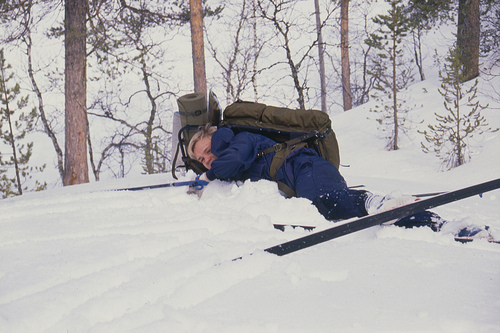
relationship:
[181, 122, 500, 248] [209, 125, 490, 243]
skier wearing suit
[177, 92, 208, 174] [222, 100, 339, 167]
bedroll on backpack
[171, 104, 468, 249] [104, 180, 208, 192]
skier has pole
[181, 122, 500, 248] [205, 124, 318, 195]
skier in jacket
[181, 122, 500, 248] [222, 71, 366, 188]
skier wearing backpack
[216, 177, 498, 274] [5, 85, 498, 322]
metal ski in snow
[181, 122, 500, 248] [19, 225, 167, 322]
skier laying on snow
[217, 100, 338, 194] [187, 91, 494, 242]
backpack of skier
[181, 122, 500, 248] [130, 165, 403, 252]
skier laying in snow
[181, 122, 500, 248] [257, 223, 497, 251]
skier wearing ski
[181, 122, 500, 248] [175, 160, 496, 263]
skier laying in snow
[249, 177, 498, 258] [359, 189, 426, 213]
ski attached to foot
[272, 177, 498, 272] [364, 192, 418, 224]
metal ski attached to ski boots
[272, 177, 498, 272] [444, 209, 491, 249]
metal ski attached to boot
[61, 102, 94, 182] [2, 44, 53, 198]
trunk of a tree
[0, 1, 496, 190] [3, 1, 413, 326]
tree trunks along mountainside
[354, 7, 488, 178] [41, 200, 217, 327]
tree saplings growing in snow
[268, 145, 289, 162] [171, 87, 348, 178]
straps of backpack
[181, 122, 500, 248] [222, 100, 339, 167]
skier carrying backpack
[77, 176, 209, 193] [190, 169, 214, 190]
pole on wrist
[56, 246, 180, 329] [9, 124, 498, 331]
tracks in snow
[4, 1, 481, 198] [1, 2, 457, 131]
trees in background